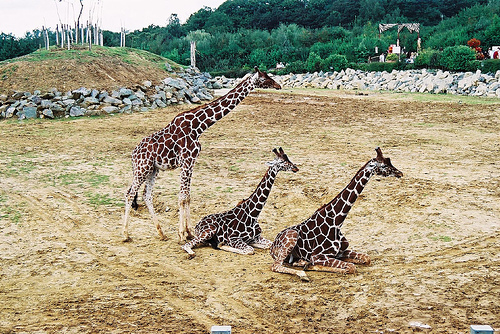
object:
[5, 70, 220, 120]
rocks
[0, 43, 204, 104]
grassy mound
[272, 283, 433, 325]
dirt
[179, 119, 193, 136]
spot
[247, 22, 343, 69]
trees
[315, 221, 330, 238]
spot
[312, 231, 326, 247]
spot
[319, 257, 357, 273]
leg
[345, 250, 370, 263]
leg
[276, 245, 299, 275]
leg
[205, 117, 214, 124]
spot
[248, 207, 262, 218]
spot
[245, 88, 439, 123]
dirt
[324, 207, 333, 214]
spot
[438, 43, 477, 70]
tree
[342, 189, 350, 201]
brown spot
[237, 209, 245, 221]
brown spot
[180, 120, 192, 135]
brown spot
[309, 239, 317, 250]
brown spot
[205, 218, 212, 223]
brown spot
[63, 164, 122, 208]
grass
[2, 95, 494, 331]
ground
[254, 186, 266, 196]
spot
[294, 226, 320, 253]
spot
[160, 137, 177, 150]
spot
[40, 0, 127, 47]
trees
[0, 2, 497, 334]
nature park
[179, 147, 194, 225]
legs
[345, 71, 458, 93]
white rocks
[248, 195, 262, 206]
spot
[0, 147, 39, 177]
grass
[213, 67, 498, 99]
wall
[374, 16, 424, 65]
structure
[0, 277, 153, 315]
dirt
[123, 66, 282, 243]
animal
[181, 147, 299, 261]
animal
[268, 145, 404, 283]
animal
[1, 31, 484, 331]
pen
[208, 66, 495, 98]
stone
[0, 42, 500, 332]
area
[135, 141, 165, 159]
spots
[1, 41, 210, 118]
mound